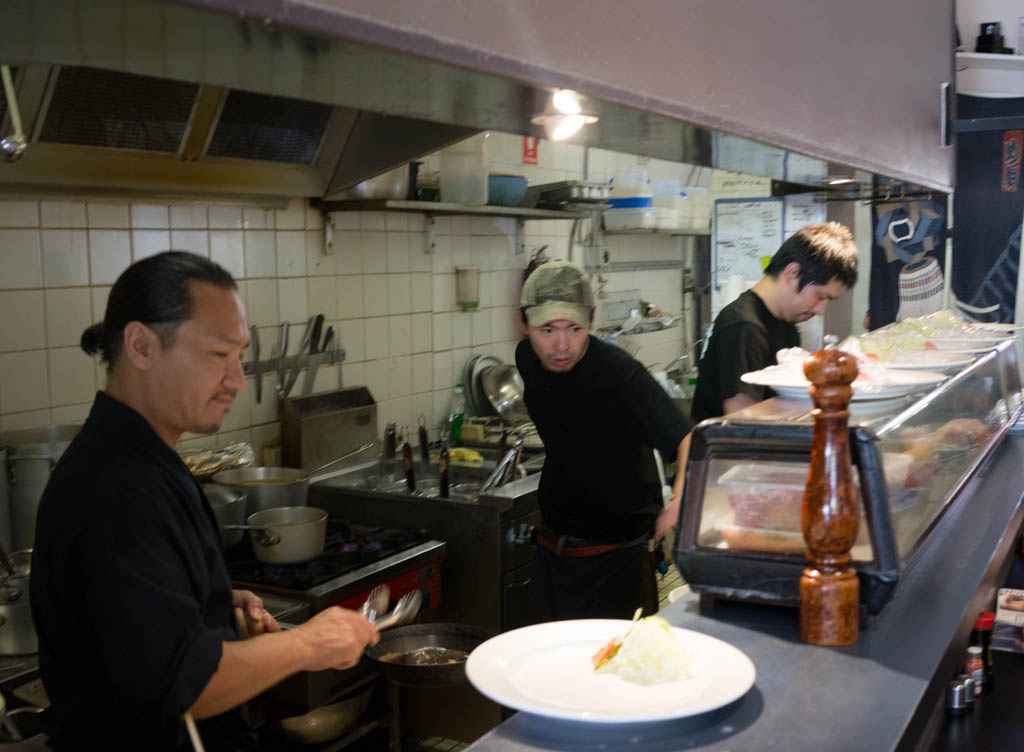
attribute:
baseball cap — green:
[498, 257, 610, 337]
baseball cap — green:
[524, 256, 598, 330]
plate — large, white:
[463, 607, 752, 737]